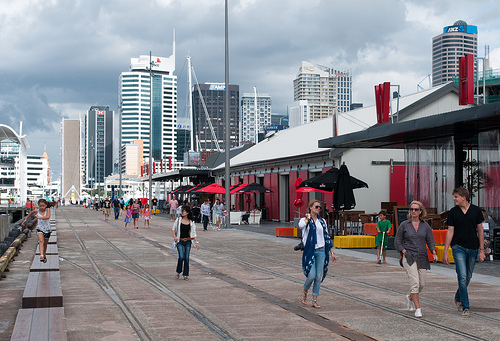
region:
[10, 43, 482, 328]
pedestrians on a city walkway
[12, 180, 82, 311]
girl running on top of benches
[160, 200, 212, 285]
woman walking while looking to her side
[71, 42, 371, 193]
skyscrapers in the background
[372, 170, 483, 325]
man and woman walking in step together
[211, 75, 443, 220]
white building with red doors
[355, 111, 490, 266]
roof above clear partitions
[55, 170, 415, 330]
metal tracks on walkway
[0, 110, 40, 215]
white building with curved roof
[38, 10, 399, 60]
grey clouds fill sky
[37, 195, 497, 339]
the street that people are walking down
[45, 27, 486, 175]
assorted skyscrapers in the background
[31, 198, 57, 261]
a girl running along the benches on the side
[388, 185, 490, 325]
a couple walking down the street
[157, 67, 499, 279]
assorted businesses on the side of the street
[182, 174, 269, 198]
a row of umbrellas in front of the store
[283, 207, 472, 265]
assorted tables in front of the shop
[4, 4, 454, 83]
the cloudy sky above the street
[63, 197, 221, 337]
the trolley tracks above the street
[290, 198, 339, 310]
a woman walking down the street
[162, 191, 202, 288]
Girl walking on a sidewalk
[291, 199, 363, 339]
Woman with sunglasses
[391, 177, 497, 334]
Two people walking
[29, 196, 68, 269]
Girl running on a bench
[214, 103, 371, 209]
Roof on a building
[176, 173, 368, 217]
Umbrellas over a table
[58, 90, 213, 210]
Buildings in a city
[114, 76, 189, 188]
White building with glass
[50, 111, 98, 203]
White and brown building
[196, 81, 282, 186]
Two buildings in a city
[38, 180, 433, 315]
people walking on the boardwalk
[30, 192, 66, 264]
a girl hopping on the bench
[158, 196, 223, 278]
a woman walking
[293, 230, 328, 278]
a womans scarf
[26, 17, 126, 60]
very cloudy skies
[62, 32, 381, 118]
tall building in the back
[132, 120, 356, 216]
a restaurant by the beac h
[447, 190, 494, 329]
man looking left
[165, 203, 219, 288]
woman looking left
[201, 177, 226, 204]
red umbrella by the shop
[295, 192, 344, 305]
woman with blue jeans on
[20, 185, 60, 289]
girl running on the benches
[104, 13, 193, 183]
tall building in the background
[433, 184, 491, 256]
man with a black shirt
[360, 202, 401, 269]
boy with a scooter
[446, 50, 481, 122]
red h on a building roof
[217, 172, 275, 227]
black and red umbrellas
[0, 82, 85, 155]
clouds in the sky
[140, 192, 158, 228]
little girl with white shorts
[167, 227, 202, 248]
woman with a brown belt